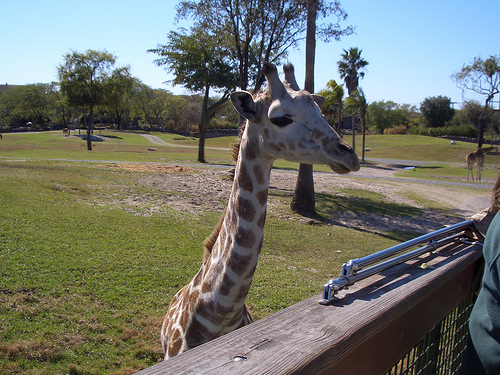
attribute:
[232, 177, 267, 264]
neck — long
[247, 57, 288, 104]
horn — green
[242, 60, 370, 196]
head — stretched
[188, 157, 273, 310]
neck — spotted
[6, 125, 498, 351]
grass — green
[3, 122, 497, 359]
park — green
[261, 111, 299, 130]
eye — dark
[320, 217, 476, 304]
metal — silver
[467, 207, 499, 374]
jumper — green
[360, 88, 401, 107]
clouds — white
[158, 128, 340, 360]
fur — brown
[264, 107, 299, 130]
eye — black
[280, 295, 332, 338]
fence — wooden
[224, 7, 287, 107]
trees — some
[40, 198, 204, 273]
grass — scarce